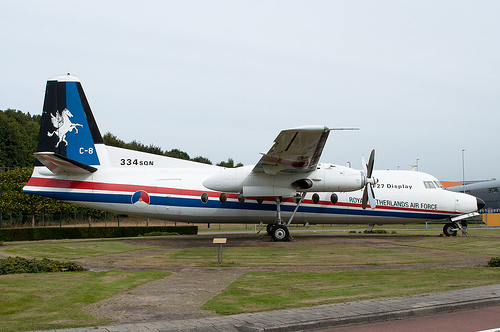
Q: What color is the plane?
A: White.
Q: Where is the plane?
A: On the grass.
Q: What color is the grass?
A: Green.